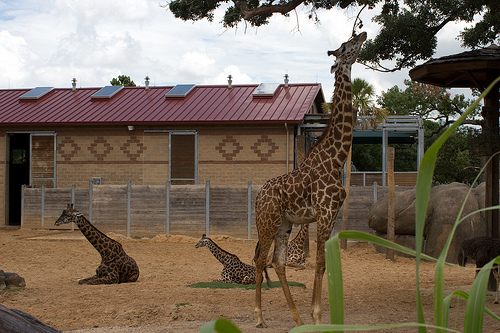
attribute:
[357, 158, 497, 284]
rock — big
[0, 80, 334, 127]
roof — red, shingled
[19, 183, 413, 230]
fence — wooden, large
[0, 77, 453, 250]
building — large